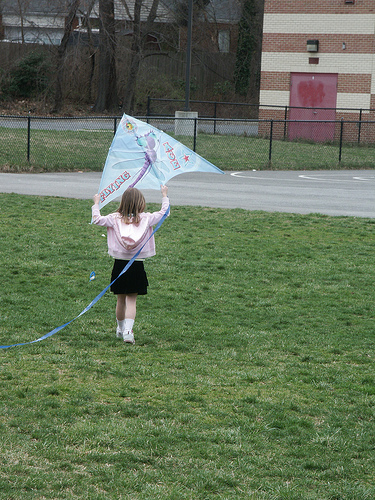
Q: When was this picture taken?
A: During the day.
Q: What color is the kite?
A: White.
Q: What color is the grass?
A: Green.